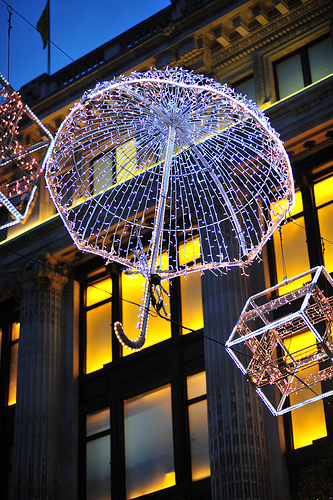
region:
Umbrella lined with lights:
[43, 62, 297, 351]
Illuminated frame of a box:
[224, 265, 331, 417]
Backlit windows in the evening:
[2, 165, 331, 498]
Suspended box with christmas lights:
[218, 271, 331, 417]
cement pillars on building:
[10, 204, 272, 499]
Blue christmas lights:
[42, 70, 296, 283]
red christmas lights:
[234, 282, 331, 402]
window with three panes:
[79, 369, 207, 498]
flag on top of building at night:
[28, 0, 59, 81]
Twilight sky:
[0, 0, 172, 93]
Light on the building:
[104, 276, 206, 404]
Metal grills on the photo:
[240, 307, 316, 396]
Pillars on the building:
[205, 381, 271, 469]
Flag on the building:
[34, 7, 65, 71]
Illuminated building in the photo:
[136, 394, 198, 485]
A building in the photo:
[67, 240, 223, 381]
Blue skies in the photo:
[70, 10, 103, 41]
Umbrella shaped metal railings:
[111, 91, 236, 222]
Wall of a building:
[94, 362, 156, 390]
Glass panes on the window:
[131, 395, 179, 463]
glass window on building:
[91, 158, 114, 189]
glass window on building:
[112, 139, 136, 182]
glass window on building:
[229, 77, 255, 117]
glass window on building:
[272, 49, 302, 99]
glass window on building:
[305, 34, 330, 87]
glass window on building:
[312, 175, 331, 204]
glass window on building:
[262, 192, 301, 216]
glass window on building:
[273, 210, 312, 291]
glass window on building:
[314, 202, 331, 271]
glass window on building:
[121, 252, 168, 354]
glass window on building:
[82, 408, 111, 431]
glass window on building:
[83, 438, 111, 497]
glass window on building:
[120, 385, 175, 493]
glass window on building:
[186, 374, 207, 396]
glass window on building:
[184, 398, 213, 483]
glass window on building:
[84, 278, 112, 300]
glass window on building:
[85, 307, 113, 365]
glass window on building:
[174, 232, 199, 262]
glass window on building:
[176, 265, 206, 334]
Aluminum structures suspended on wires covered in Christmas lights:
[0, 74, 331, 416]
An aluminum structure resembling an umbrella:
[45, 65, 295, 350]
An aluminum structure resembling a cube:
[224, 264, 330, 413]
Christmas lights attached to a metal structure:
[236, 263, 244, 274]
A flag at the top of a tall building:
[33, 0, 45, 73]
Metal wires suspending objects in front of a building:
[1, 1, 74, 80]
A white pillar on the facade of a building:
[16, 250, 77, 497]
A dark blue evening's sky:
[0, 0, 170, 100]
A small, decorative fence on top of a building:
[19, 0, 201, 107]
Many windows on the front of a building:
[1, 31, 331, 497]